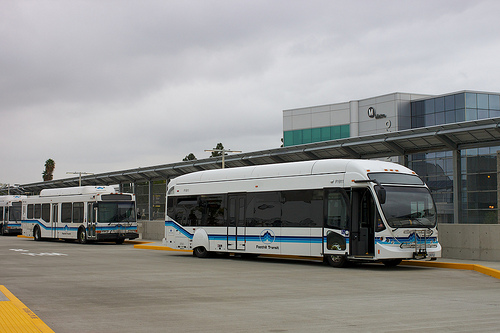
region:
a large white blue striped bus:
[163, 161, 441, 265]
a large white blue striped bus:
[21, 185, 136, 243]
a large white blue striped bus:
[0, 195, 29, 233]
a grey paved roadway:
[1, 229, 498, 330]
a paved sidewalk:
[434, 255, 497, 271]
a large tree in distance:
[43, 157, 54, 181]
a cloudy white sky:
[0, 1, 497, 188]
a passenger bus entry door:
[348, 184, 373, 256]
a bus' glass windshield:
[373, 183, 433, 225]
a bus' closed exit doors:
[225, 191, 245, 248]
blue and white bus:
[171, 147, 466, 318]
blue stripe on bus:
[164, 188, 324, 263]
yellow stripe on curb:
[200, 246, 483, 294]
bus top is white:
[184, 162, 411, 209]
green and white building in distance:
[266, 98, 427, 148]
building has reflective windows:
[412, 84, 494, 157]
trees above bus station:
[46, 152, 240, 181]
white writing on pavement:
[0, 236, 95, 293]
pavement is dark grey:
[17, 238, 145, 327]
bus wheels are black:
[193, 239, 204, 263]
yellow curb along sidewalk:
[439, 258, 492, 280]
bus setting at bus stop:
[153, 154, 448, 271]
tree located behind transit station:
[34, 148, 62, 184]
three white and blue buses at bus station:
[2, 153, 446, 279]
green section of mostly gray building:
[272, 117, 369, 159]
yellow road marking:
[3, 268, 59, 331]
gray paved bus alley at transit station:
[2, 226, 498, 331]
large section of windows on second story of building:
[405, 83, 499, 147]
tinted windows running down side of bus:
[165, 185, 387, 239]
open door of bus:
[324, 175, 390, 264]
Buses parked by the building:
[2, 81, 476, 321]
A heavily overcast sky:
[39, 24, 231, 110]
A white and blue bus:
[155, 158, 466, 263]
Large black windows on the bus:
[167, 188, 341, 225]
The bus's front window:
[374, 180, 444, 229]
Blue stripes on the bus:
[202, 231, 329, 246]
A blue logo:
[253, 224, 281, 256]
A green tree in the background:
[38, 155, 67, 180]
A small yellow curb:
[430, 259, 495, 281]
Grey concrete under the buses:
[106, 267, 268, 327]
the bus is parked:
[139, 147, 458, 284]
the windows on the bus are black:
[157, 186, 329, 225]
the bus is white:
[101, 127, 456, 272]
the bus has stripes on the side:
[192, 224, 319, 250]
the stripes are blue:
[197, 225, 317, 247]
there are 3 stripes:
[219, 228, 316, 246]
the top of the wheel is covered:
[177, 223, 212, 259]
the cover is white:
[188, 225, 211, 255]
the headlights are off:
[371, 225, 443, 252]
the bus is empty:
[133, 165, 436, 283]